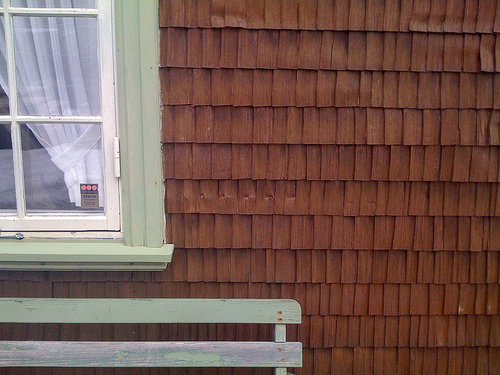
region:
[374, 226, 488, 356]
A brown wood wall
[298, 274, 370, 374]
A brown wood wall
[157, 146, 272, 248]
A brown wood wall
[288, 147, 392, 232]
A brown wood wall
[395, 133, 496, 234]
A brown wood wall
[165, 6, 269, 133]
A brown wood wall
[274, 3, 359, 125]
A brown wood wall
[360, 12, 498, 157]
A brown wood wall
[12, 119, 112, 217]
A clear glass window pane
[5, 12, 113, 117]
A clear glass window pane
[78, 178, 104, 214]
A sign with three dots.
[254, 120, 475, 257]
Brown shingles on a wall.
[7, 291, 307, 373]
A weather beaten bench.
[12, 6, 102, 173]
White sheer curtains hanging in a window.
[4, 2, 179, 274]
A green weather washed window frame.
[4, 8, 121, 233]
A multiple pane window painted white.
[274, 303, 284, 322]
Nail holes in a bench.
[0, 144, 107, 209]
A bed with a white spread.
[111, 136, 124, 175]
The hinge joint on an outside window.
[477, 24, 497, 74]
A loose brown shingle hanging from the wall.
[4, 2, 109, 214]
this is a window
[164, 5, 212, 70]
these are wall blocks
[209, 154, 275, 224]
these are wall blocks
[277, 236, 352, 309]
these are wall blocks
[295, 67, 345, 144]
these are wall blocks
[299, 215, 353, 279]
these are wall blocks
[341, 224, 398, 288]
these are wall blocks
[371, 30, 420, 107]
these are wall blocks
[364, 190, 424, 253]
these are wall blocks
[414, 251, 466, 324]
these are wall blocks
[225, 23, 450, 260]
brown side to wall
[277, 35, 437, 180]
brown wooden pieces on wall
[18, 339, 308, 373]
second back board to bench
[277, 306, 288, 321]
rusty screws in benc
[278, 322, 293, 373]
side post of bench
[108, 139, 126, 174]
white hinge on window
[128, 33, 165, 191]
blue frame on window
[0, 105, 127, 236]
window on side of building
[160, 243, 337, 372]
a bench against a wall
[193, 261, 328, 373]
a wooden bench against a wall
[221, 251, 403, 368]
a bench agianst the building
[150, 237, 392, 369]
a wooden bench against the building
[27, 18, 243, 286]
a window with curtains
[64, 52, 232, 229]
curtains in a window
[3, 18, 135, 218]
white curtains in a window